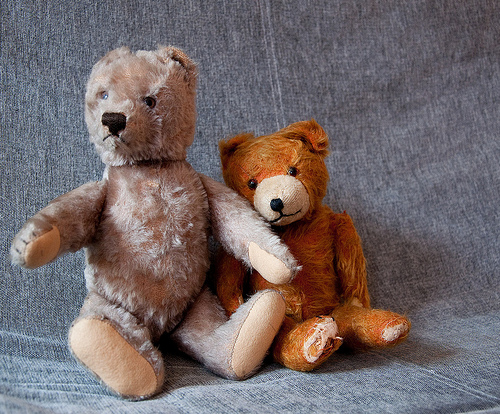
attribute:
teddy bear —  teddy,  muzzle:
[214, 119, 413, 374]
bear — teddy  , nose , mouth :
[1, 38, 317, 383]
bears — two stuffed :
[25, 3, 347, 260]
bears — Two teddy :
[81, 43, 412, 354]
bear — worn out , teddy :
[206, 120, 411, 372]